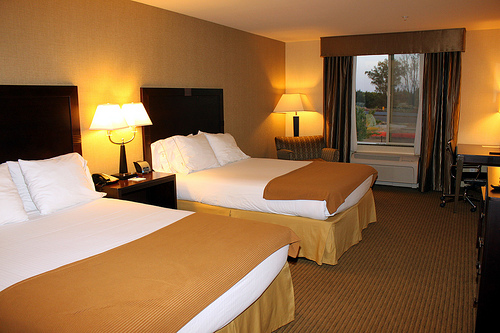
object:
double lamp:
[89, 102, 153, 180]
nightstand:
[99, 169, 176, 209]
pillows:
[204, 132, 248, 167]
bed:
[149, 130, 378, 264]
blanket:
[262, 159, 379, 214]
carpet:
[267, 185, 483, 333]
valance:
[320, 27, 466, 56]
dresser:
[473, 166, 500, 333]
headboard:
[140, 87, 225, 171]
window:
[355, 54, 387, 144]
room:
[0, 0, 498, 332]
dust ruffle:
[177, 187, 377, 265]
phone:
[91, 172, 120, 186]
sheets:
[174, 157, 373, 220]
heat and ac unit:
[349, 158, 417, 189]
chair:
[273, 136, 341, 162]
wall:
[0, 0, 287, 178]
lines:
[298, 138, 303, 160]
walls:
[284, 28, 500, 144]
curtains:
[418, 28, 460, 191]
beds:
[0, 153, 297, 333]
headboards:
[1, 85, 83, 162]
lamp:
[272, 93, 315, 136]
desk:
[453, 142, 500, 212]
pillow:
[173, 136, 220, 172]